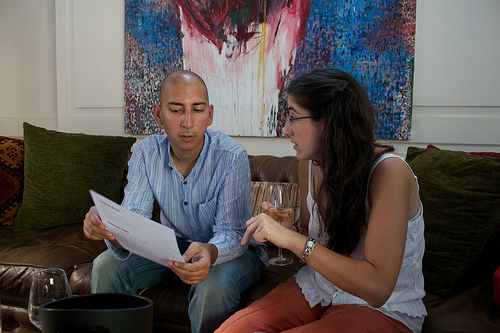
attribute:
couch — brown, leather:
[1, 136, 500, 331]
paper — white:
[88, 188, 185, 269]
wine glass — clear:
[266, 182, 291, 264]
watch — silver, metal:
[299, 237, 317, 266]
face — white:
[307, 240, 315, 249]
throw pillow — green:
[13, 121, 136, 232]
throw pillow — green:
[405, 146, 500, 292]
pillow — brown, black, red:
[1, 136, 25, 231]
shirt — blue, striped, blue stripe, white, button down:
[103, 130, 253, 267]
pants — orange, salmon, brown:
[213, 272, 412, 332]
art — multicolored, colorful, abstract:
[125, 0, 417, 141]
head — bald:
[152, 70, 214, 151]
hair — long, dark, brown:
[288, 67, 393, 256]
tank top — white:
[294, 153, 426, 333]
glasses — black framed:
[287, 110, 313, 124]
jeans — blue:
[91, 234, 262, 333]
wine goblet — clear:
[28, 268, 73, 333]